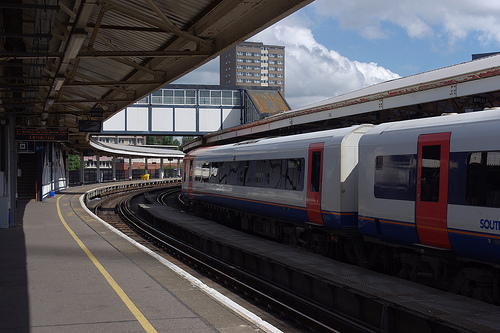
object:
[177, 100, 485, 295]
passenger train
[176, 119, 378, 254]
car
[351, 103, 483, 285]
car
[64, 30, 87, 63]
light fixture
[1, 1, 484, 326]
train station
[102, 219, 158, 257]
edge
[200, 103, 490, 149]
roof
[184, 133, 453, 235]
door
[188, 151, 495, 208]
window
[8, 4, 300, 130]
ceiling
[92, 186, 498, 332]
track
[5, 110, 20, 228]
pole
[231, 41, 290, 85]
building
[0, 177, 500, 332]
platform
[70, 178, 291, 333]
line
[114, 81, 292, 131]
bridge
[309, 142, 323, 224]
stripe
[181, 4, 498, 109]
sky